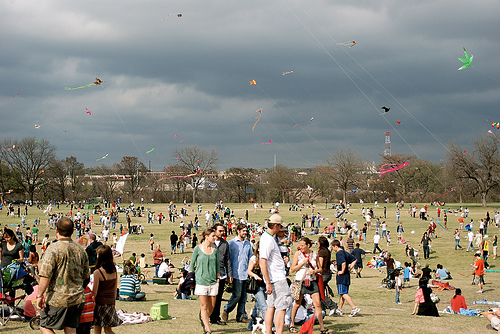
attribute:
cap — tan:
[268, 212, 286, 229]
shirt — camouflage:
[43, 241, 92, 303]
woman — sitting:
[120, 265, 146, 299]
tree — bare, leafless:
[7, 139, 55, 210]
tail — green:
[64, 81, 96, 91]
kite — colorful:
[93, 75, 103, 88]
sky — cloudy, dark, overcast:
[4, 4, 499, 157]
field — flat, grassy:
[4, 204, 497, 334]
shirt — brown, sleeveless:
[97, 276, 117, 303]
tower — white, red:
[383, 127, 392, 159]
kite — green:
[453, 47, 478, 74]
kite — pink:
[377, 158, 408, 176]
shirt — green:
[193, 243, 220, 285]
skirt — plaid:
[97, 303, 120, 324]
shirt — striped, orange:
[78, 287, 94, 322]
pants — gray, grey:
[35, 299, 85, 330]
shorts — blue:
[335, 283, 351, 295]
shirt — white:
[262, 234, 286, 280]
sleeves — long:
[188, 245, 200, 275]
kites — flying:
[247, 69, 314, 154]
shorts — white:
[192, 283, 222, 297]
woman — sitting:
[409, 276, 438, 316]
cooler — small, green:
[152, 302, 172, 322]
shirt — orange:
[453, 295, 467, 311]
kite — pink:
[259, 135, 273, 147]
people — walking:
[201, 217, 288, 329]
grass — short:
[357, 296, 389, 330]